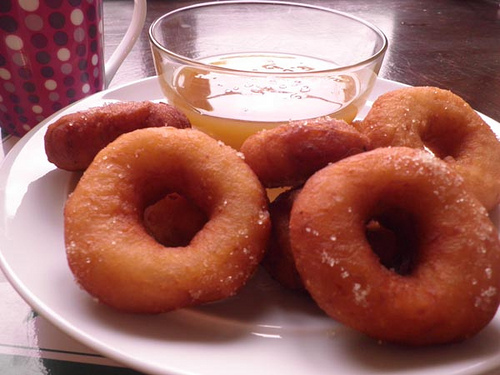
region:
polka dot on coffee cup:
[31, 32, 50, 47]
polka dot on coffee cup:
[56, 47, 72, 59]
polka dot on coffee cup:
[46, 80, 58, 88]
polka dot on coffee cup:
[31, 105, 44, 113]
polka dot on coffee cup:
[89, 52, 99, 63]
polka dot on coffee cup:
[80, 82, 90, 92]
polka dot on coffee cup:
[61, 62, 74, 72]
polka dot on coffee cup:
[62, 75, 72, 88]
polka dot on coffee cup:
[67, 87, 78, 96]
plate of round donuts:
[33, 3, 495, 365]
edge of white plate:
[66, 325, 142, 366]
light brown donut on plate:
[68, 118, 257, 346]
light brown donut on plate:
[287, 170, 484, 349]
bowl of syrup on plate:
[146, 4, 371, 122]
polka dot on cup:
[46, 80, 61, 91]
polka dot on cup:
[64, 62, 76, 74]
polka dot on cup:
[21, 80, 38, 92]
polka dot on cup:
[39, 77, 60, 87]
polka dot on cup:
[81, 80, 92, 93]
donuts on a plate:
[72, 130, 457, 364]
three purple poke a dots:
[28, 28, 56, 80]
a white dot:
[3, 29, 26, 54]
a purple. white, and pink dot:
[52, 30, 74, 77]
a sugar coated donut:
[279, 201, 377, 312]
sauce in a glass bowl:
[194, 48, 257, 135]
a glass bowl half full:
[191, 53, 356, 116]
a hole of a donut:
[121, 164, 226, 251]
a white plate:
[43, 312, 277, 367]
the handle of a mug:
[87, 18, 143, 92]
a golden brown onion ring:
[287, 141, 498, 341]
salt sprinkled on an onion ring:
[309, 227, 375, 315]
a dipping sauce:
[157, 7, 382, 116]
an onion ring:
[64, 128, 274, 315]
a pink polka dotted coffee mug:
[0, 2, 151, 142]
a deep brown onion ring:
[46, 103, 189, 163]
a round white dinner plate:
[4, 76, 498, 372]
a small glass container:
[146, 3, 392, 135]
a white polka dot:
[59, 48, 69, 63]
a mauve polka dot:
[46, 9, 66, 29]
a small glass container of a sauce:
[150, 0, 395, 157]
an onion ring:
[295, 146, 498, 346]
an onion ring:
[34, 99, 196, 164]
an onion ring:
[240, 115, 366, 185]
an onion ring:
[372, 75, 498, 209]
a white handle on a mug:
[101, 0, 146, 81]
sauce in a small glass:
[173, 53, 367, 133]